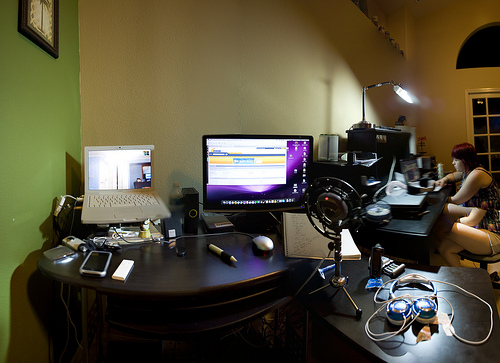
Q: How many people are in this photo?
A: 1.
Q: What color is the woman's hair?
A: Red.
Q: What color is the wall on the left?
A: Green.